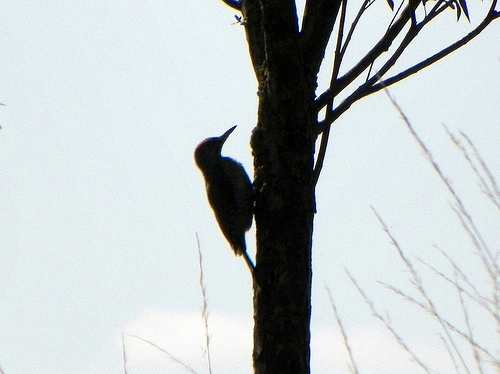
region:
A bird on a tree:
[190, 124, 272, 288]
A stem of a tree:
[250, 301, 320, 367]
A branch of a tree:
[337, 4, 442, 153]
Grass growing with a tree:
[392, 205, 498, 356]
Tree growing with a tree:
[153, 50, 474, 372]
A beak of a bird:
[216, 122, 242, 142]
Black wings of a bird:
[215, 177, 242, 239]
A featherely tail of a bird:
[236, 249, 256, 278]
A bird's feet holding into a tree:
[251, 174, 259, 216]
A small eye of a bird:
[207, 147, 213, 152]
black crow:
[160, 113, 302, 283]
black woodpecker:
[149, 67, 289, 329]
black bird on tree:
[188, 39, 385, 358]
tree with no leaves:
[370, 95, 497, 350]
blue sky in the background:
[48, 42, 475, 372]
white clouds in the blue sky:
[98, 229, 212, 371]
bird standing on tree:
[174, 117, 353, 350]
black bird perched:
[152, 88, 380, 305]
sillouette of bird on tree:
[213, 11, 429, 371]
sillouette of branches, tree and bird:
[301, 6, 460, 160]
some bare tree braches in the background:
[318, 87, 498, 372]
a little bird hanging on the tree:
[191, 125, 258, 270]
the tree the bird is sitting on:
[220, 2, 499, 364]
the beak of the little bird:
[216, 123, 241, 143]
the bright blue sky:
[2, 2, 212, 372]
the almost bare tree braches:
[304, 2, 497, 123]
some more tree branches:
[111, 223, 219, 371]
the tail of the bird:
[223, 220, 255, 281]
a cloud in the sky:
[127, 300, 412, 372]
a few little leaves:
[439, 2, 473, 19]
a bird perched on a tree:
[191, 124, 265, 282]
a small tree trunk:
[251, 3, 316, 373]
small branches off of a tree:
[315, 1, 498, 163]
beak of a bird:
[221, 123, 236, 141]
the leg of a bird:
[237, 246, 255, 281]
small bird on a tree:
[193, 126, 266, 276]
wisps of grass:
[326, 86, 498, 371]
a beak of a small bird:
[219, 125, 236, 146]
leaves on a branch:
[447, 0, 472, 24]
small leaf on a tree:
[230, 13, 244, 26]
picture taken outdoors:
[86, 54, 465, 371]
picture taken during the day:
[76, 84, 437, 323]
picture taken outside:
[78, 64, 420, 291]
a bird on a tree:
[180, 79, 386, 369]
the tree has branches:
[271, 40, 481, 66]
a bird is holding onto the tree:
[196, 107, 330, 271]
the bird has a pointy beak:
[196, 87, 283, 190]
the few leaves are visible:
[353, 4, 488, 39]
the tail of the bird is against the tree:
[229, 236, 289, 314]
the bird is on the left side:
[170, 119, 266, 232]